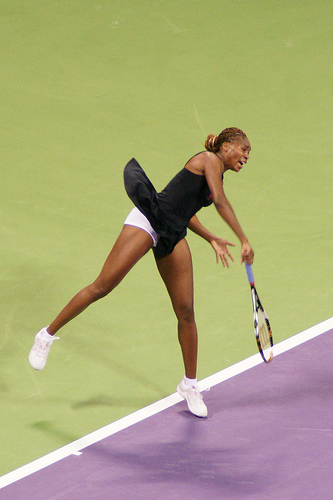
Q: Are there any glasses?
A: No, there are no glasses.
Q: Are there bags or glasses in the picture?
A: No, there are no glasses or bags.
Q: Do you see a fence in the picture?
A: No, there are no fences.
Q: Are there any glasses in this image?
A: No, there are no glasses.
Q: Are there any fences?
A: No, there are no fences.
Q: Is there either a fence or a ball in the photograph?
A: No, there are no fences or balls.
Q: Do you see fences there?
A: No, there are no fences.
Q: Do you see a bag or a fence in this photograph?
A: No, there are no fences or bags.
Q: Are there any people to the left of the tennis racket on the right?
A: Yes, there is a person to the left of the racket.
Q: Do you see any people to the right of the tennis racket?
A: No, the person is to the left of the tennis racket.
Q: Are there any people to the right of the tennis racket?
A: No, the person is to the left of the tennis racket.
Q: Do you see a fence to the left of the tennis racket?
A: No, there is a person to the left of the tennis racket.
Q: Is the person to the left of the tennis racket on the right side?
A: Yes, the person is to the left of the tennis racket.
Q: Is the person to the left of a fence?
A: No, the person is to the left of the tennis racket.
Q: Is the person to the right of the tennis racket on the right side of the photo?
A: No, the person is to the left of the racket.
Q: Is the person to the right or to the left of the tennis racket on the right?
A: The person is to the left of the racket.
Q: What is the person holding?
A: The person is holding the tennis racket.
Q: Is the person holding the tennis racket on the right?
A: Yes, the person is holding the tennis racket.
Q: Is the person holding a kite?
A: No, the person is holding the tennis racket.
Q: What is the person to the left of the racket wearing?
A: The person is wearing a dress.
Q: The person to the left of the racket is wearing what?
A: The person is wearing a dress.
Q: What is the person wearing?
A: The person is wearing a dress.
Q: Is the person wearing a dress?
A: Yes, the person is wearing a dress.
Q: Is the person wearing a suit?
A: No, the person is wearing a dress.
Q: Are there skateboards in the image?
A: No, there are no skateboards.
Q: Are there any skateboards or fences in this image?
A: No, there are no skateboards or fences.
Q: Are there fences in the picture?
A: No, there are no fences.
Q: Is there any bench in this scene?
A: No, there are no benches.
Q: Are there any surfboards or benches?
A: No, there are no benches or surfboards.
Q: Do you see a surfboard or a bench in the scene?
A: No, there are no benches or surfboards.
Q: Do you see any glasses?
A: No, there are no glasses.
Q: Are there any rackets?
A: Yes, there is a racket.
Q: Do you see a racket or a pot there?
A: Yes, there is a racket.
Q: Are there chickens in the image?
A: No, there are no chickens.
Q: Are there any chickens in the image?
A: No, there are no chickens.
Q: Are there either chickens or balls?
A: No, there are no chickens or balls.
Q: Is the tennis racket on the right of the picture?
A: Yes, the tennis racket is on the right of the image.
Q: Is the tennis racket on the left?
A: No, the tennis racket is on the right of the image.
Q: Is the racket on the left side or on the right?
A: The racket is on the right of the image.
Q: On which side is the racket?
A: The racket is on the right of the image.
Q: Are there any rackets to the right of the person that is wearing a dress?
A: Yes, there is a racket to the right of the person.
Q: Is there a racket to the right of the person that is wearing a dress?
A: Yes, there is a racket to the right of the person.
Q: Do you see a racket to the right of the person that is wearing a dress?
A: Yes, there is a racket to the right of the person.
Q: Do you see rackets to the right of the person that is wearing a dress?
A: Yes, there is a racket to the right of the person.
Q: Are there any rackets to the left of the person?
A: No, the racket is to the right of the person.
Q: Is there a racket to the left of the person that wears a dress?
A: No, the racket is to the right of the person.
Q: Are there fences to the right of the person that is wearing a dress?
A: No, there is a racket to the right of the person.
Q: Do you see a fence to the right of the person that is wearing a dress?
A: No, there is a racket to the right of the person.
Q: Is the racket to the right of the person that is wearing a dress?
A: Yes, the racket is to the right of the person.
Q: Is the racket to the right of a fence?
A: No, the racket is to the right of the person.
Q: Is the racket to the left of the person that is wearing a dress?
A: No, the racket is to the right of the person.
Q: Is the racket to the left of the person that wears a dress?
A: No, the racket is to the right of the person.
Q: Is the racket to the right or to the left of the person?
A: The racket is to the right of the person.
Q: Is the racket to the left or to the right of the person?
A: The racket is to the right of the person.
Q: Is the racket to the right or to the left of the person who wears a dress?
A: The racket is to the right of the person.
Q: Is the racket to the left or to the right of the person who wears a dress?
A: The racket is to the right of the person.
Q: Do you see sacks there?
A: No, there are no sacks.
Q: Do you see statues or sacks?
A: No, there are no sacks or statues.